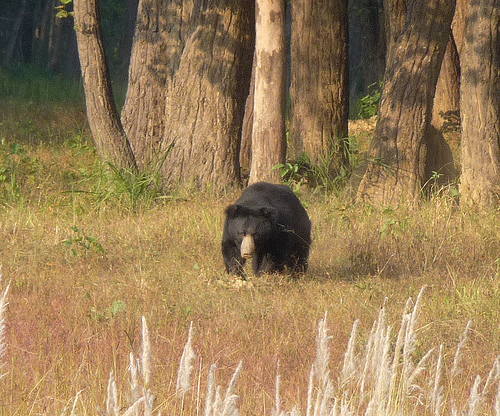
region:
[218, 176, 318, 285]
large furry black bear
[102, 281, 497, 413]
tall light tan straw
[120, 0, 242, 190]
big brown tree trunk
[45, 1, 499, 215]
grouping of large trees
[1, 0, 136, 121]
shadowy forested area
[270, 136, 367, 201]
small cluster of green leaves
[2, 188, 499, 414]
area of golden colored grasses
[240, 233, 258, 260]
black bear's tan nose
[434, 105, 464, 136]
dark shadow on tree trunk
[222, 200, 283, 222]
black bears fuzzy ears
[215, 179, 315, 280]
a black bear facing the camera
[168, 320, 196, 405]
white tufts on a plant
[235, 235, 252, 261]
nose of the bear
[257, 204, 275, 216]
left ear of the bear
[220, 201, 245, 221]
right ear of the bear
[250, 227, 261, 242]
left eye of the bear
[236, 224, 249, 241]
right eye of the bear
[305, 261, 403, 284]
shadow of the bear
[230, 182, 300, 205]
back of the bear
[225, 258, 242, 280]
leg of the bear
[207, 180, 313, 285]
this is a bear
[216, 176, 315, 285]
the bear is black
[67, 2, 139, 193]
a brown tree trunk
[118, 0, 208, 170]
a brown tree trunk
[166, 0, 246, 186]
a brown tree trunk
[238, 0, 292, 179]
a brown tree trunk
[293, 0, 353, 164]
a brown tree trunk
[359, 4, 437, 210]
a brown tree trunk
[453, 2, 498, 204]
a brown tree trunk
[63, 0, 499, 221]
brown tree trunks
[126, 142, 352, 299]
black bear walking through tan grass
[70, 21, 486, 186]
thick and thin tree trunks behind bear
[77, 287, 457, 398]
thin plumes of white plant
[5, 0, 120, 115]
dark forest in background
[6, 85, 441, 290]
green plants springing up through grasses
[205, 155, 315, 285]
hexagonal shape of furry perimeter of body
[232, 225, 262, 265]
think and long tan snout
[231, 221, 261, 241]
small and dark close-set eyes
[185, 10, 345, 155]
tree bark different from the trunks on either side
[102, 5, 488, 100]
shadow of leaves falling across the trunks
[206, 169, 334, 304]
black bear in field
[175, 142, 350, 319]
black bear walking across field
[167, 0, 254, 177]
large brown tree trunk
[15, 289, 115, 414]
field covered in brown grass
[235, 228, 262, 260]
tan snout of bear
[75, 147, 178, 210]
green bushes growing under tree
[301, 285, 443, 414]
white buds on tall plants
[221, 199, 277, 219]
ears of black bear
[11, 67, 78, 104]
green grass growing under trees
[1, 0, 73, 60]
thick forest